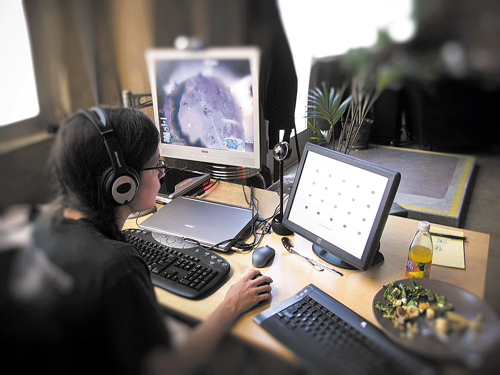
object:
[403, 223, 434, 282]
beverage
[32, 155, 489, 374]
desk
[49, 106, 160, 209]
hair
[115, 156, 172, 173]
glass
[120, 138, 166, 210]
face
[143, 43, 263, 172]
monitor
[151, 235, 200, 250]
pad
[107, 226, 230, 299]
keyboard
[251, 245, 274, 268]
mouse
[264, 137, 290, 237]
plant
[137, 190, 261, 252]
laptop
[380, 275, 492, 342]
food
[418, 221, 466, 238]
notepad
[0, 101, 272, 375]
woman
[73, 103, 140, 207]
earphone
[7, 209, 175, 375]
shirt